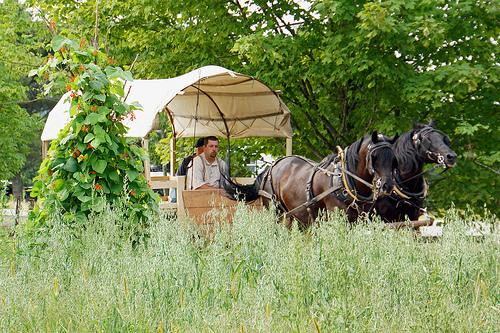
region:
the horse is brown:
[264, 127, 378, 220]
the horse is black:
[385, 119, 495, 234]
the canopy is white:
[39, 24, 301, 184]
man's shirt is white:
[188, 141, 228, 182]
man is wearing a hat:
[188, 129, 204, 149]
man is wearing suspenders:
[186, 157, 240, 184]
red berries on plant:
[35, 12, 167, 277]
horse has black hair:
[403, 115, 430, 182]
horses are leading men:
[240, 121, 497, 262]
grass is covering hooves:
[200, 197, 497, 332]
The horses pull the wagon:
[247, 120, 497, 231]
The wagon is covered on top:
[22, 67, 314, 181]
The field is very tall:
[132, 252, 365, 329]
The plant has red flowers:
[28, 46, 163, 247]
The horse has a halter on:
[352, 135, 408, 215]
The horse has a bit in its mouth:
[437, 154, 462, 165]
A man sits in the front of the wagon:
[177, 128, 237, 191]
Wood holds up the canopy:
[185, 72, 291, 130]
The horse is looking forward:
[382, 112, 469, 187]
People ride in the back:
[146, 137, 203, 169]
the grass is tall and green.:
[163, 217, 483, 331]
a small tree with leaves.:
[29, 16, 169, 256]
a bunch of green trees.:
[15, 12, 495, 124]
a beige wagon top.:
[25, 57, 297, 149]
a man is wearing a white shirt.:
[191, 162, 225, 189]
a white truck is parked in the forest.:
[413, 202, 498, 252]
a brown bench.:
[179, 187, 277, 234]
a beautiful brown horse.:
[266, 127, 397, 233]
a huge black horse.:
[398, 111, 470, 213]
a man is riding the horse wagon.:
[8, 45, 485, 326]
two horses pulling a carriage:
[254, 118, 456, 225]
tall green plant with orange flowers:
[23, 21, 154, 244]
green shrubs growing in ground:
[3, 196, 495, 331]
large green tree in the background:
[235, 2, 412, 154]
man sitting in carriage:
[184, 136, 225, 195]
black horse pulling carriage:
[358, 118, 458, 225]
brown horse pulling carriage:
[259, 127, 398, 225]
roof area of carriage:
[41, 69, 291, 139]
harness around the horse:
[256, 143, 355, 218]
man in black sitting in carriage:
[178, 133, 206, 178]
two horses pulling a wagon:
[119, 62, 461, 262]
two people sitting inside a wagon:
[171, 126, 228, 208]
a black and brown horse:
[266, 129, 403, 225]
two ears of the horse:
[367, 126, 402, 148]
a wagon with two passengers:
[43, 68, 300, 236]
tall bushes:
[225, 203, 336, 328]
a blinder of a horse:
[417, 135, 432, 150]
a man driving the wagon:
[186, 133, 230, 198]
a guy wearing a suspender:
[194, 137, 224, 177]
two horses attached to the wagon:
[136, 65, 462, 243]